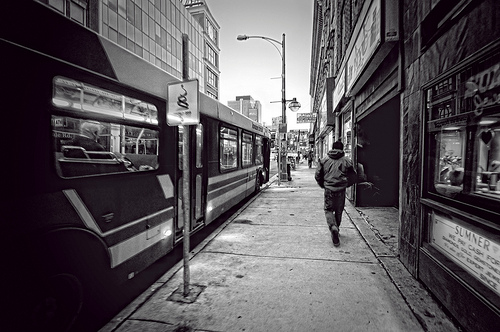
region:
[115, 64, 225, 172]
a sign on a pole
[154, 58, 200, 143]
a sign on a metal pole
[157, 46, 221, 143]
a pole with a sign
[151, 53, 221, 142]
metal pole with a sign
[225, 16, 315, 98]
a light on a pole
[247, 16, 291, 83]
a light on a metal pole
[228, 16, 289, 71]
a pole with a light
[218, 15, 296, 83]
a metal pole with a light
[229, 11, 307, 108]
street light with a pole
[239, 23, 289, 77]
street light with a metal pole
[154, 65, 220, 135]
a black and white sign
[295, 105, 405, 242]
a person walking on sidewalk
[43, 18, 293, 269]
a long bus at the curb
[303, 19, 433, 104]
a sign on a building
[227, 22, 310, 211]
a street light pole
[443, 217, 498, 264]
sumner on the sign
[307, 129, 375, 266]
a jacket and pants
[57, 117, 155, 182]
a person on the bus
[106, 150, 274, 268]
white lines on the bus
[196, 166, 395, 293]
lines in the sidewalk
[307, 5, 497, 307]
storefronts behind worn sidewalk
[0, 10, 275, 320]
striped city bus by curb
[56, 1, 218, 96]
building covered with panels in back of bus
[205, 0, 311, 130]
clear sky over city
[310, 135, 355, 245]
man in hooded jacket walking down street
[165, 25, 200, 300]
sign with swirled design on pole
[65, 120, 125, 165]
passenger seated in rear of bus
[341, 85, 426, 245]
large entryway to building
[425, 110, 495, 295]
small windows over rectangular sign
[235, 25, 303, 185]
lamppost with light for street and sidewalk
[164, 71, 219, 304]
sigh on sidewalk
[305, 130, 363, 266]
man walking down sidewalk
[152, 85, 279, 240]
bus stopped at bus stop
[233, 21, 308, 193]
street light on sidewalk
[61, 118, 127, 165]
person sitting on bus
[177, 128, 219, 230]
closed door on bus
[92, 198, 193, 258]
white stripe on bus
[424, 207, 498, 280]
sign on side of building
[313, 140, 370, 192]
man wearing dark jacket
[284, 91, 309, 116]
lamp over sidewalk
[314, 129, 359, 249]
Man walking on the sidewalk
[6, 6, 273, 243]
Bus parked along sidewalk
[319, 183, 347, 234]
Man wearing dark pants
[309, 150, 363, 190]
Man wearing a jacket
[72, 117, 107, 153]
Person sitting inside the bus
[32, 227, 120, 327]
Back tire of the bus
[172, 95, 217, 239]
Side door of the bus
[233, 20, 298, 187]
Street light pole is not illuminated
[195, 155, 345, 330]
A long concrete sidewalk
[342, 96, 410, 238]
Archway to a business